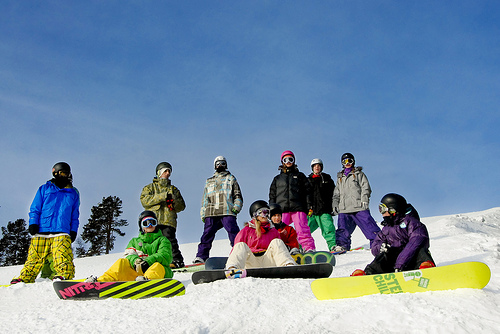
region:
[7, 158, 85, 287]
Man wearing a blue jacket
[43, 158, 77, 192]
Black mask on man's face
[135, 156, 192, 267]
Man wearing a green jacket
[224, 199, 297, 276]
Girl wearing white pants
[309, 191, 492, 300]
Girl sitting in the snow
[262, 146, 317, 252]
Woman wearing a black jacket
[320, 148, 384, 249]
Girl wearing purple pants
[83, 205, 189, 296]
Woman sitting in the snow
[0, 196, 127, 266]
Trees behind the man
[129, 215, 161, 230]
Goggles on girl's face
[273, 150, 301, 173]
The man's helmet is pink.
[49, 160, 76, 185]
The man's helmet is black.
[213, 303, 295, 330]
The snow in the forefront is white.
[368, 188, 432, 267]
The person's jacket is purple.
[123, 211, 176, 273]
The person's jacket is green.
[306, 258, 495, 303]
The snowboard is yellow and green.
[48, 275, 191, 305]
The snowboard is yellow, black and pink.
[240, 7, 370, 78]
The sky is blue.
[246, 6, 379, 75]
The sky is clear.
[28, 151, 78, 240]
The person is wearing a blue jacket.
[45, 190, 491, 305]
People sitting in the snow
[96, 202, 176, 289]
A person wearing a green coat.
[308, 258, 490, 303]
A yellow and green snowboard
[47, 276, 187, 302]
A black, yellow, and pink snowboard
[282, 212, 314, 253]
A pair of pink pants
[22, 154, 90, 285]
A person standing in a blue coat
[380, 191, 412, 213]
A black helmet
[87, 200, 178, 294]
A person wearing goggles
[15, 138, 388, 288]
People standing in the snow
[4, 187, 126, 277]
Evergreen trees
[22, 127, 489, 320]
people posing in the snow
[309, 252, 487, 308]
yellow snowboard in the snow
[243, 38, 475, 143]
blue sky in the distance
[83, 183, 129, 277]
green tree behind the people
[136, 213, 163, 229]
goggles on a snowboarder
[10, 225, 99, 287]
yellow plaid pants on a snowboarder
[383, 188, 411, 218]
black helmet on a snowboarder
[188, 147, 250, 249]
man standing in the snow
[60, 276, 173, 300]
design on a snowboard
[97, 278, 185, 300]
yellow and black stripes on the bottom of a snowboard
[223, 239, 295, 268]
girl wearing white snowpants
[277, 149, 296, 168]
person wearing a pink helmet and blue goggles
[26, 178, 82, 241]
person in a blue coat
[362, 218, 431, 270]
person in a purple coat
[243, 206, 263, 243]
girl with blonde hair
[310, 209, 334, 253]
person wearing green snowpants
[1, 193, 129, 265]
green trees on a snowy slope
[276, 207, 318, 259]
person wearing pink snowpants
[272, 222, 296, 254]
person wearing a red coat